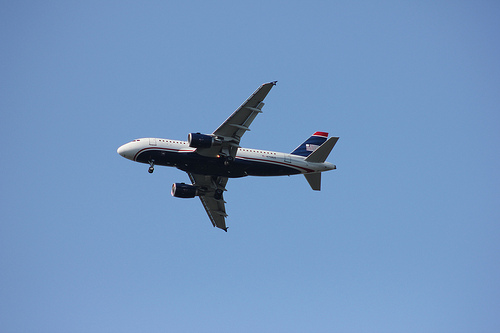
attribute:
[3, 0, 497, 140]
sky — section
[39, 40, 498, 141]
blue sky — clear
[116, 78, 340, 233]
plane — flying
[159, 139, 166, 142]
window — passenger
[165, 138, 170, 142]
window — passenger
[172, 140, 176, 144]
window — passenger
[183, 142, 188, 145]
window — passenger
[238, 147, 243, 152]
window — passenger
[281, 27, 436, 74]
sky — section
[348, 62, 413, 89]
sky — hazy blue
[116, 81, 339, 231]
jet — white, large, blue, red, passenger jet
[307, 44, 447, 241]
no altitude — high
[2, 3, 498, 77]
sky — section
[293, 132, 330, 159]
tail — blue, red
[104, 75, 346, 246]
plane — body is white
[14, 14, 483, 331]
sky — clear, blue, section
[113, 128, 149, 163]
pit — cock